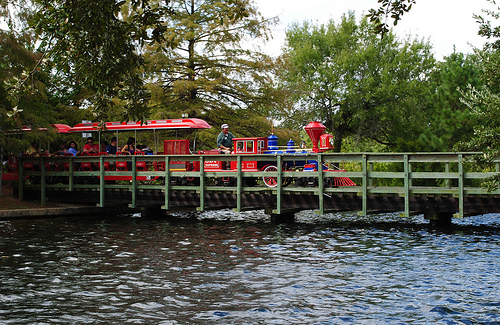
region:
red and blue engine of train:
[235, 117, 339, 185]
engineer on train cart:
[210, 116, 232, 155]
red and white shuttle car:
[78, 122, 204, 153]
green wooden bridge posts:
[164, 154, 470, 199]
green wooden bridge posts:
[42, 155, 213, 203]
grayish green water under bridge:
[38, 227, 387, 324]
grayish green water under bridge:
[360, 226, 470, 307]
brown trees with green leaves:
[7, 7, 173, 101]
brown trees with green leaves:
[153, 8, 268, 105]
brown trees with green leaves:
[286, 5, 481, 120]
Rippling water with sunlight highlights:
[36, 235, 366, 310]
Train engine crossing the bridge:
[232, 116, 357, 189]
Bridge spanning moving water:
[361, 133, 498, 245]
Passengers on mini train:
[16, 122, 174, 192]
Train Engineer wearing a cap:
[207, 105, 324, 186]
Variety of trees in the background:
[6, 3, 497, 140]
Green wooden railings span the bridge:
[21, 156, 498, 218]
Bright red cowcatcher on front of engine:
[325, 154, 367, 202]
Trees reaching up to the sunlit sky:
[264, 5, 490, 72]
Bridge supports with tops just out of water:
[142, 197, 489, 239]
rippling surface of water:
[30, 225, 345, 320]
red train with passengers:
[1, 115, 366, 192]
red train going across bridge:
[0, 120, 491, 230]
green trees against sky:
[235, 7, 495, 122]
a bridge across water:
[5, 155, 496, 275]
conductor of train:
[205, 112, 365, 207]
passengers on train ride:
[0, 115, 207, 155]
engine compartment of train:
[262, 123, 378, 209]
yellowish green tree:
[157, 4, 262, 116]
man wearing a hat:
[212, 115, 245, 155]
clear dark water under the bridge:
[90, 236, 336, 316]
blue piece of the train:
[256, 122, 325, 183]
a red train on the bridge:
[17, 111, 386, 219]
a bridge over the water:
[5, 132, 497, 250]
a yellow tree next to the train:
[97, 10, 299, 130]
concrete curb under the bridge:
[0, 203, 99, 224]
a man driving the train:
[205, 112, 257, 174]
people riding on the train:
[27, 127, 160, 170]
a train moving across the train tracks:
[19, 109, 446, 211]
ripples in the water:
[67, 232, 310, 299]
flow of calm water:
[17, 235, 317, 315]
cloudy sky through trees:
[370, 0, 490, 60]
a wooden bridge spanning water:
[366, 136, 496, 226]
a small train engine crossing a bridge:
[235, 111, 370, 211]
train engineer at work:
[211, 112, 357, 192]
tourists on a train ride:
[10, 117, 175, 177]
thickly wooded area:
[25, 65, 445, 111]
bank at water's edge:
[0, 192, 117, 227]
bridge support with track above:
[405, 190, 472, 232]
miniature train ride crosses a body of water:
[17, 78, 472, 229]